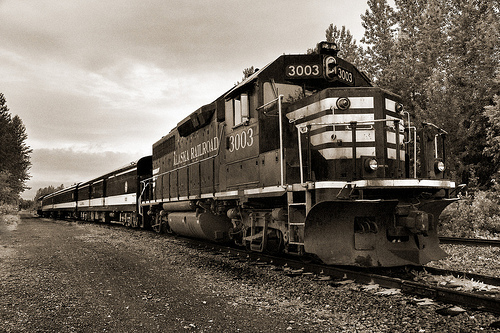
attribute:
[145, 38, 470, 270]
engine — black, locomotive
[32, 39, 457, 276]
train — black, white, metalic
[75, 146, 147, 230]
car — box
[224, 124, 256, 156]
number — 3003, white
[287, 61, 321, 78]
number — 3003, white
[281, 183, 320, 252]
ladder — short, small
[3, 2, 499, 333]
photograph — black, white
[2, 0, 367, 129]
sky — cloudy, bright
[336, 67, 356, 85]
number — 3003, white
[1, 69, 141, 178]
clouds — white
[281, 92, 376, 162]
strips — white